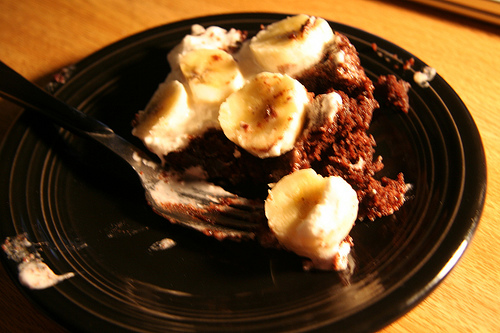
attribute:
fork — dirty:
[1, 61, 275, 242]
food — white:
[217, 70, 309, 159]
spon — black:
[28, 93, 245, 238]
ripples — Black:
[25, 19, 465, 331]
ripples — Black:
[164, 300, 240, 331]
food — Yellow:
[193, 43, 365, 205]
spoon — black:
[0, 59, 278, 247]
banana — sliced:
[245, 147, 384, 292]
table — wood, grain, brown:
[0, 1, 497, 330]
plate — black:
[14, 39, 466, 331]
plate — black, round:
[2, 11, 486, 330]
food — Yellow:
[214, 68, 317, 155]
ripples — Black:
[277, 292, 336, 322]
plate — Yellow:
[29, 27, 499, 316]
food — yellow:
[174, 102, 350, 270]